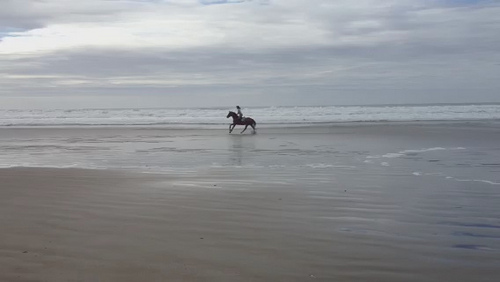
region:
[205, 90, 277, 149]
Person on a horse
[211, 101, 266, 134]
person riding a horse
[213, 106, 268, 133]
Person on a horse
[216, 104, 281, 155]
Horse in the sand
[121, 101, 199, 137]
waves hitting the sand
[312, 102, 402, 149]
waves hitting the sand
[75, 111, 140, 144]
waves hitting the sand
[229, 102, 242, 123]
woman on a horse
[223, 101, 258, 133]
horse running through sand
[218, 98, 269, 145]
horse being ridden on beach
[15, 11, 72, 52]
white clouds in blue sky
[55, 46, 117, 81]
white clouds in blue sky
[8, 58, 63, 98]
white clouds in blue sky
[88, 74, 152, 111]
white clouds in blue sky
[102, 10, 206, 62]
white clouds in blue sky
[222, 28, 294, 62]
white clouds in blue sky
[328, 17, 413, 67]
white clouds in blue sky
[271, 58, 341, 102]
white clouds in blue sky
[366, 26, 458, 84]
white clouds in blue sky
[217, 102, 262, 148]
brown horse running on beach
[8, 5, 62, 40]
white clouds in blue sky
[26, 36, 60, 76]
white clouds in blue sky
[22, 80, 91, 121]
white clouds in blue sky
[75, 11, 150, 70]
white clouds in blue sky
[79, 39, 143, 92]
white clouds in blue sky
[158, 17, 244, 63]
white clouds in blue sky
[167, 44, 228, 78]
white clouds in blue sky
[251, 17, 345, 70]
white clouds in blue sky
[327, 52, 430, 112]
white clouds in blue sky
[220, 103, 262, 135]
a woman riding a horse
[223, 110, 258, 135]
a dark colored horse running along the beach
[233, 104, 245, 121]
a woman sitting on top of a horse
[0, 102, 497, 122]
waves forming in the ocean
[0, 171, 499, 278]
wet sand on the beach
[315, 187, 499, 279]
ripples in the sand from the water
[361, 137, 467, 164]
froth in the water from the waves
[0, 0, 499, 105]
a cloudy and overcast sky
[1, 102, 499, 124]
the ocean in the distance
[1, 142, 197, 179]
water lapping up onto the shore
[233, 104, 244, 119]
a person mounted on a horse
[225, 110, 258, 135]
a dark colored horse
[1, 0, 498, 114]
mostly overcast sky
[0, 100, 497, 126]
turbulent ocean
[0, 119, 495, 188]
wet sand where the waves broke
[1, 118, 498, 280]
a sandy, mostly empty beach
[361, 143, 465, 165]
a small line of white foam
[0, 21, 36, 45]
a small gap in the cloud cover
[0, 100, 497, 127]
foam where the surf is breaking